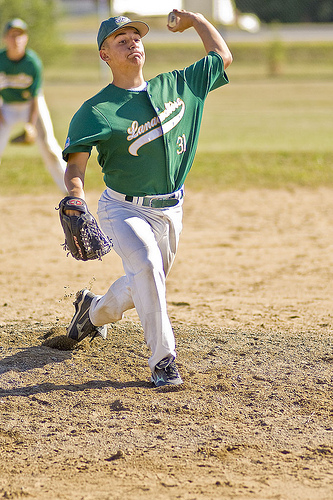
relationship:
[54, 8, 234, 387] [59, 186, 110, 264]
man has glove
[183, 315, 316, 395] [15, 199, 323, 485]
dirt on field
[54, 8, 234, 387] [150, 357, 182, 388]
man has feet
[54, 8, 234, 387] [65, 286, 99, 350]
man has foot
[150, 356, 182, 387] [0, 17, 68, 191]
shoe of man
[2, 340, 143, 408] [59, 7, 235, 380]
shadow from man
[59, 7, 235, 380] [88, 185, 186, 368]
man wearing pants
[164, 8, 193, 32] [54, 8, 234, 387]
hand of a man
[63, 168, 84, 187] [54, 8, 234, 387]
elbow on man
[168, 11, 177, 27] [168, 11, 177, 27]
ball with ball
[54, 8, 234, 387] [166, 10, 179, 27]
man pitching ball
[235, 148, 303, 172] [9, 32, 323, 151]
grass on an outfield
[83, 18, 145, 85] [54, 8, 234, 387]
head of a man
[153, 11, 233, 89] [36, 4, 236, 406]
arm of a person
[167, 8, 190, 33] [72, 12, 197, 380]
hand of a person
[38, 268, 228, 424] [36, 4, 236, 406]
feet of a person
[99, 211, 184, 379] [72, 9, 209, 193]
leg of a person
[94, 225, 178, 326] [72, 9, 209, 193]
leg of a person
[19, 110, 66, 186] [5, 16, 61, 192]
leg of a person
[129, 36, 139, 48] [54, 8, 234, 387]
nose of a man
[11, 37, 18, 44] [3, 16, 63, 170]
nose of a person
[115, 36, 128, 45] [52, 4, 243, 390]
eye of a person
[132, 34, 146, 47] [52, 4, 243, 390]
eye of a person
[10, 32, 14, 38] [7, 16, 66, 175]
eye of a person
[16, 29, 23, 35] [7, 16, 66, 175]
eye of a person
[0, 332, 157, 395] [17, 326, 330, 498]
shadow on ground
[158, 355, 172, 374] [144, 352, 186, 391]
lace on shoe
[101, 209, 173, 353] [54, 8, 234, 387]
leg of man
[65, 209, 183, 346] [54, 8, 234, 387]
leg of man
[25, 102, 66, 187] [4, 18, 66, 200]
leg of person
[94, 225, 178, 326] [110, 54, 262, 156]
leg of person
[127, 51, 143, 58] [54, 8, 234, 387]
mouth of man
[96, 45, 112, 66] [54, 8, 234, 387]
ear of man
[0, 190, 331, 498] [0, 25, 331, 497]
dirt of ground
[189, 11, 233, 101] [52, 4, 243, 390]
arm of person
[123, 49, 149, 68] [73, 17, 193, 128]
mouth of person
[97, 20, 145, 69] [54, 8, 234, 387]
face of man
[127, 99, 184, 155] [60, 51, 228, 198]
name on jersey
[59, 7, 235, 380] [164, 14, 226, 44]
man throwing ball